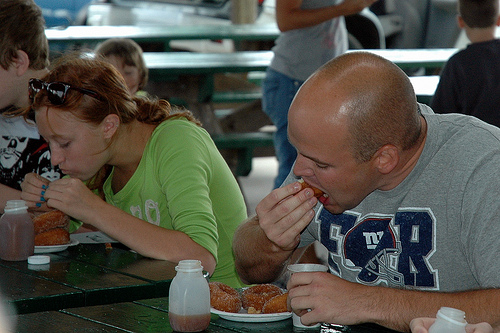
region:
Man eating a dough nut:
[275, 173, 326, 213]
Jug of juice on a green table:
[158, 243, 220, 331]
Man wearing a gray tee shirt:
[403, 129, 491, 286]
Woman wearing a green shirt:
[123, 106, 243, 254]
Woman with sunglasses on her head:
[21, 65, 89, 130]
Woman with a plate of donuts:
[30, 199, 86, 271]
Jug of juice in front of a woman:
[9, 193, 31, 275]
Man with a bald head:
[276, 45, 423, 153]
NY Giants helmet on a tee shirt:
[333, 223, 415, 293]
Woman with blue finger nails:
[29, 183, 56, 208]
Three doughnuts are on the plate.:
[209, 281, 300, 322]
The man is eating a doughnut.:
[234, 48, 443, 240]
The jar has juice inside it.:
[153, 255, 222, 331]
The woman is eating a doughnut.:
[15, 61, 200, 256]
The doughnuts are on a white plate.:
[204, 278, 289, 322]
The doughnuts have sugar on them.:
[208, 280, 295, 323]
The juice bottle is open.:
[3, 198, 59, 299]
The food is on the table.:
[46, 256, 282, 331]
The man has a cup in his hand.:
[274, 251, 345, 331]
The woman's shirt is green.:
[87, 113, 247, 263]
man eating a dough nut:
[272, 161, 365, 252]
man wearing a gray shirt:
[302, 190, 494, 305]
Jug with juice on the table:
[164, 254, 227, 331]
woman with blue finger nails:
[26, 178, 59, 218]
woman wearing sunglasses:
[17, 70, 134, 129]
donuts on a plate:
[11, 183, 80, 258]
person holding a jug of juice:
[408, 299, 485, 331]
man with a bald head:
[296, 44, 417, 158]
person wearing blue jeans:
[251, 55, 332, 187]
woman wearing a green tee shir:
[140, 148, 244, 262]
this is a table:
[72, 283, 141, 321]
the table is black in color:
[106, 309, 138, 324]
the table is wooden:
[85, 310, 117, 321]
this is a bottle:
[165, 254, 213, 331]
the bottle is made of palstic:
[173, 278, 192, 298]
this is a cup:
[291, 260, 328, 321]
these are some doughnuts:
[214, 279, 279, 310]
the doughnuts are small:
[213, 285, 265, 305]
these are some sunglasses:
[20, 78, 110, 115]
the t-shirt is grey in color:
[452, 194, 475, 206]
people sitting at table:
[0, 2, 497, 329]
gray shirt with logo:
[277, 102, 497, 330]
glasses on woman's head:
[25, 76, 107, 108]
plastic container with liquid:
[2, 195, 32, 260]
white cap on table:
[28, 253, 50, 264]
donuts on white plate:
[211, 281, 297, 321]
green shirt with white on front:
[103, 122, 244, 282]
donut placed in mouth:
[255, 178, 320, 247]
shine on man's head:
[320, 55, 380, 120]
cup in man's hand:
[283, 260, 328, 331]